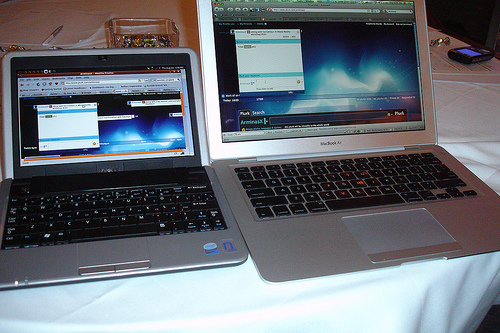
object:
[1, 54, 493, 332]
cloth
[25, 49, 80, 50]
pen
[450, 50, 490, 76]
phone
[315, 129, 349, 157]
sign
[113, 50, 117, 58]
bowl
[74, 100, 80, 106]
camera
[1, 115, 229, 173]
laptop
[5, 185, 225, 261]
keyboard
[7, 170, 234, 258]
keyboard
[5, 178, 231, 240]
laptop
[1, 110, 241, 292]
keyboard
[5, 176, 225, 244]
keyboard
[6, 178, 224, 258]
cellphone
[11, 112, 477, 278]
computers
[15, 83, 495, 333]
table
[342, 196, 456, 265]
mouse buttons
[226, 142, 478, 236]
keyboard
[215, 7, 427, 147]
display screen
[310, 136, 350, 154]
manufacturer logo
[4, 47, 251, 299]
notebook computer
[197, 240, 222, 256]
software sticker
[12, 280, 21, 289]
indicator light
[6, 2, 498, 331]
tabletop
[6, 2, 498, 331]
tablecloth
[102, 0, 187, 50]
container